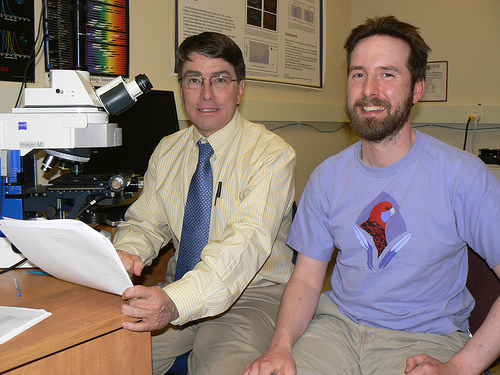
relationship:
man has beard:
[247, 19, 499, 374] [348, 108, 412, 138]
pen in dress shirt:
[214, 181, 224, 205] [112, 109, 297, 325]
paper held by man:
[2, 214, 136, 296] [113, 33, 298, 375]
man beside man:
[247, 19, 499, 374] [113, 33, 298, 375]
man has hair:
[247, 19, 499, 374] [345, 18, 434, 80]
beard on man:
[348, 108, 412, 138] [247, 19, 499, 374]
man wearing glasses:
[113, 33, 298, 375] [182, 74, 240, 88]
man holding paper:
[113, 33, 298, 375] [2, 214, 136, 296]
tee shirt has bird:
[286, 132, 499, 330] [361, 200, 397, 255]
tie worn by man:
[173, 143, 216, 279] [113, 33, 298, 375]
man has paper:
[113, 33, 298, 375] [2, 214, 136, 296]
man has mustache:
[247, 19, 499, 374] [354, 99, 392, 105]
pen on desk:
[11, 274, 25, 299] [0, 250, 159, 367]